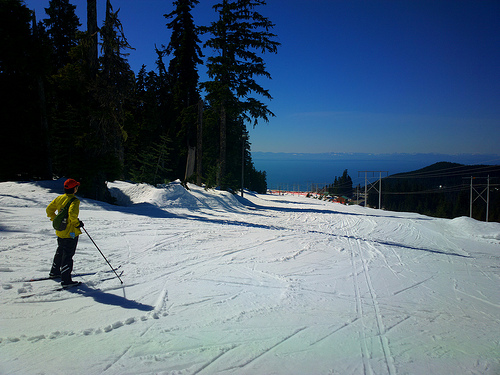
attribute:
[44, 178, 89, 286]
skier — looking, enjoying view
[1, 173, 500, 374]
field — snow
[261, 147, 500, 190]
mountains — background, distant, small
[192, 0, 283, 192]
trees — green, tall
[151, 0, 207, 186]
trees — green, tall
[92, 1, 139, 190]
trees — green, to the left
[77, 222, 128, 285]
pole — black, ski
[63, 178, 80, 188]
cap — red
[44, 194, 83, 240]
coat — yellow, neon yellow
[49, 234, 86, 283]
pants — black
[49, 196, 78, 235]
bag — black, dark green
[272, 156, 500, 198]
lines — power, electrical, distance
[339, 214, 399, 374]
tracks — few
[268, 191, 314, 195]
fence — bright orange, orange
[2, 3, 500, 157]
sky — deep blue, blue